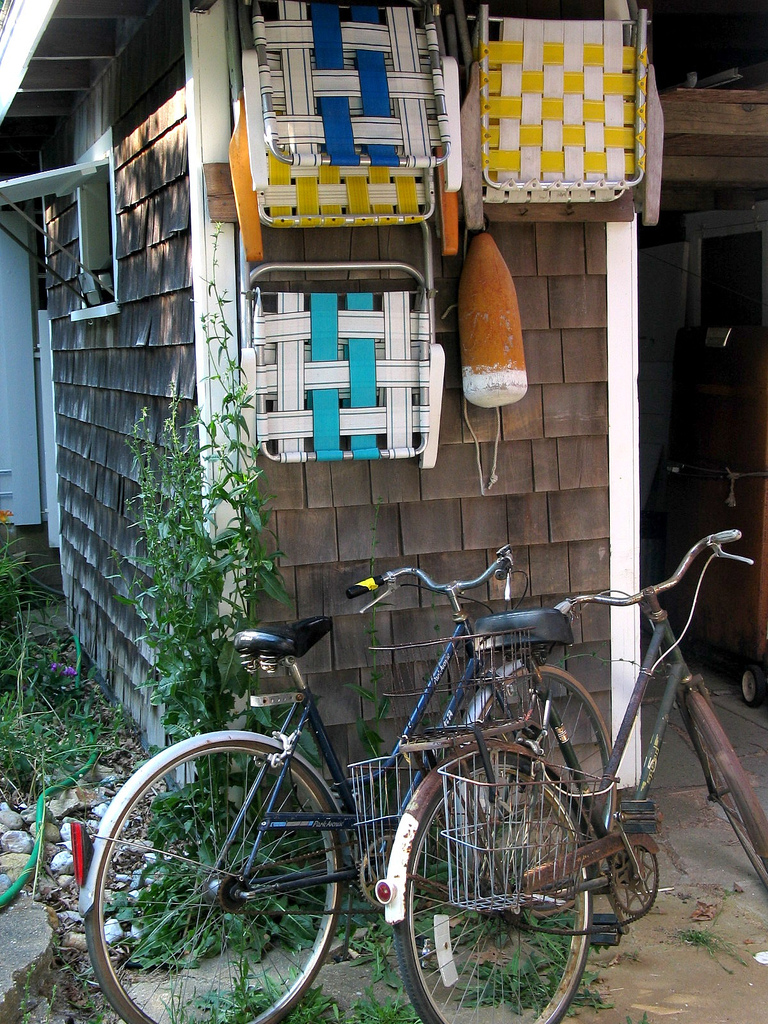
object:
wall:
[243, 221, 425, 290]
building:
[0, 0, 642, 901]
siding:
[565, 536, 608, 593]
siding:
[506, 495, 551, 552]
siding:
[456, 485, 517, 554]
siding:
[332, 496, 406, 565]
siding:
[271, 503, 344, 571]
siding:
[364, 455, 422, 507]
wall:
[253, 468, 355, 616]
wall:
[365, 455, 506, 562]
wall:
[369, 584, 447, 642]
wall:
[312, 622, 386, 756]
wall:
[389, 468, 497, 591]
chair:
[226, 0, 466, 265]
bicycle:
[373, 528, 768, 1024]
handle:
[702, 528, 745, 548]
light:
[69, 816, 96, 892]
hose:
[0, 635, 105, 914]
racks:
[230, 611, 549, 899]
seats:
[232, 614, 336, 677]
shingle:
[479, 438, 537, 499]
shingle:
[417, 440, 484, 503]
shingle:
[398, 496, 467, 557]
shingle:
[333, 499, 402, 562]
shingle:
[275, 506, 340, 569]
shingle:
[367, 451, 423, 506]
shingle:
[305, 457, 372, 511]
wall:
[450, 411, 613, 580]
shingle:
[253, 454, 307, 511]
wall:
[493, 221, 608, 412]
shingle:
[546, 273, 607, 331]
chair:
[235, 214, 449, 474]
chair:
[458, 0, 668, 236]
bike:
[65, 544, 619, 1024]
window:
[65, 123, 122, 325]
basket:
[435, 745, 605, 915]